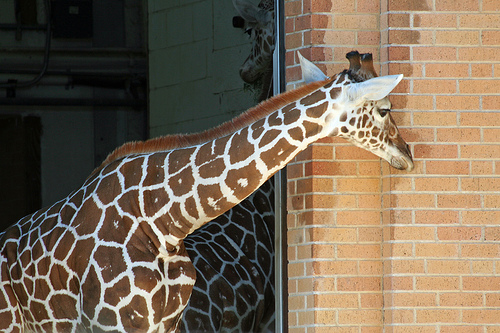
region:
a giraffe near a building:
[19, 15, 442, 324]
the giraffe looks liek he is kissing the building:
[323, 29, 438, 191]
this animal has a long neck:
[86, 77, 341, 236]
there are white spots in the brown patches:
[226, 160, 266, 203]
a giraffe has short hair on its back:
[64, 62, 326, 169]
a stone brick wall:
[295, 157, 492, 314]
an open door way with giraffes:
[22, 10, 335, 312]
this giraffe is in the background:
[216, 2, 285, 97]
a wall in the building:
[12, 21, 199, 116]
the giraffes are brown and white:
[32, 9, 432, 306]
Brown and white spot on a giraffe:
[226, 169, 272, 198]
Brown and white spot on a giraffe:
[298, 118, 325, 142]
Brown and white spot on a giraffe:
[285, 123, 300, 147]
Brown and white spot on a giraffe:
[275, 100, 297, 121]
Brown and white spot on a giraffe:
[293, 91, 339, 104]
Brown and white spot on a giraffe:
[243, 115, 275, 147]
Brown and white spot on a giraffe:
[224, 123, 265, 156]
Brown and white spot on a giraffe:
[190, 140, 232, 179]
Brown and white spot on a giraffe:
[160, 146, 203, 168]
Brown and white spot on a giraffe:
[143, 144, 175, 199]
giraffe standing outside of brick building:
[5, 44, 428, 326]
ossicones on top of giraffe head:
[335, 41, 380, 77]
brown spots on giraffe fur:
[69, 234, 142, 299]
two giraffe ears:
[283, 38, 413, 118]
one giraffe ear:
[370, 97, 398, 124]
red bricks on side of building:
[433, 55, 490, 157]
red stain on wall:
[283, 4, 353, 246]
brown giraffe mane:
[85, 80, 327, 177]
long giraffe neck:
[119, 91, 324, 248]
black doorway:
[3, 108, 58, 240]